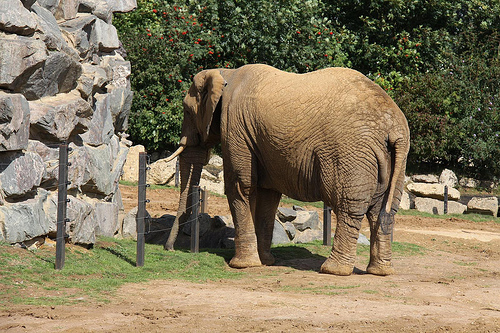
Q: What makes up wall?
A: Rocks.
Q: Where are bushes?
A: In background.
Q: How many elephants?
A: One.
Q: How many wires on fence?
A: Six.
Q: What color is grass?
A: Green.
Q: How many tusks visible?
A: One.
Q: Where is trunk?
A: On grass.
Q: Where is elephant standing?
A: On path.